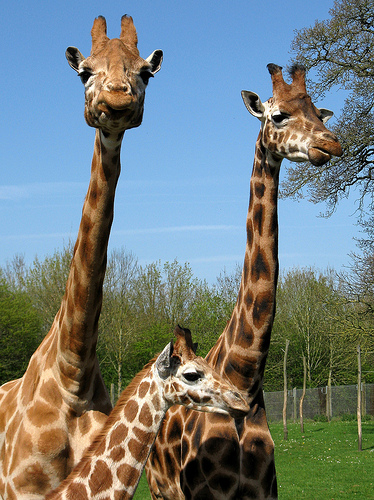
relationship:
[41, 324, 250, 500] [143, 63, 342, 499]
giraffe with a giraffe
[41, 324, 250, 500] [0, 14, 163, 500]
giraffe with a giraffe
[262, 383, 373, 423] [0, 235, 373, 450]
fence in wooded area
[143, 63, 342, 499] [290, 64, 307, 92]
giraffe has a horn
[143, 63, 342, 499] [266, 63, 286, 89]
giraffe has a horn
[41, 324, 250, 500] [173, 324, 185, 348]
giraffe has a horn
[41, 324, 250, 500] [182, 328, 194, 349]
giraffe has a horn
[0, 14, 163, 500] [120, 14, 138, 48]
giraffe has a horn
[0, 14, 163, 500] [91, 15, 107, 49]
giraffe has a horn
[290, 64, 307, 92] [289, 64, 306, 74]
horn has a tip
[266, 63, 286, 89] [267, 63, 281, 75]
horn has a tip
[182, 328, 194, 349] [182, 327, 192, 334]
horn has a tip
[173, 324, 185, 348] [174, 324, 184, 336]
horn has a tip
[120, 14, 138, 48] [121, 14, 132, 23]
horn has a tip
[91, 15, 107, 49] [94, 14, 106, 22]
horn has a tip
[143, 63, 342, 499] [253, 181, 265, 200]
giraffe has a marking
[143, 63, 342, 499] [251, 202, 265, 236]
giraffe has a marking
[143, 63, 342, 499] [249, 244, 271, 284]
giraffe has a marking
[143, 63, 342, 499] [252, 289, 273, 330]
giraffe has a marking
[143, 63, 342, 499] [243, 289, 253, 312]
giraffe has a marking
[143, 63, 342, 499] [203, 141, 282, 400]
giraffe has a neck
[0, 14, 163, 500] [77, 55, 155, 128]
giraffe has a face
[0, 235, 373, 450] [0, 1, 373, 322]
wooded area against sky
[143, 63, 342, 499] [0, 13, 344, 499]
giraffe part of a trio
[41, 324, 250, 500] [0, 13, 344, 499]
giraffe part of a trio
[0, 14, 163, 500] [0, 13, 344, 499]
giraffe part of a trio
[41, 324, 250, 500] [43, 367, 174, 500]
giraffe has a neck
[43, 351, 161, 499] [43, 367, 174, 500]
mane on neck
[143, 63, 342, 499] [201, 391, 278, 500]
giraffe has a front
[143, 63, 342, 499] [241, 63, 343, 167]
giraffe has a head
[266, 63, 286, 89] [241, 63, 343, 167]
horn on head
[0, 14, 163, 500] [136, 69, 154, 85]
giraffe has a left eye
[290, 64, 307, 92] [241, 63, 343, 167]
horn on head